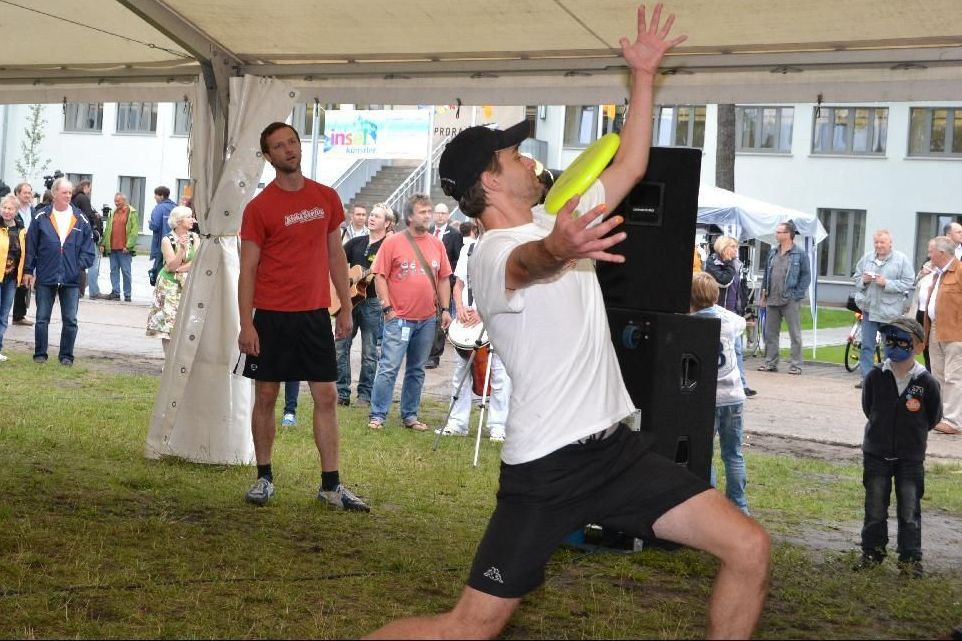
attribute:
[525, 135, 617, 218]
frisbee — yellow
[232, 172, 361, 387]
clothing — red, black 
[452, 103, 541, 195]
cap — black 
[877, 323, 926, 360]
face — blue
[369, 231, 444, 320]
shirt — red